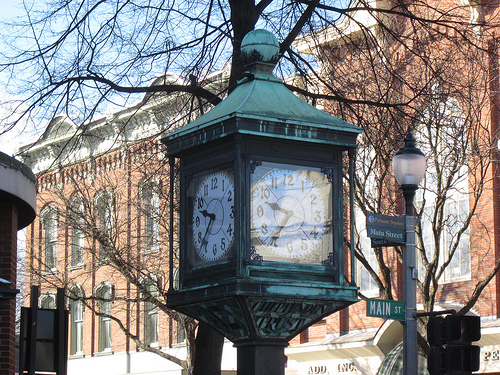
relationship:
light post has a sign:
[389, 126, 430, 374] [366, 299, 405, 320]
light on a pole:
[390, 125, 427, 195] [400, 191, 419, 374]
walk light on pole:
[425, 311, 482, 374] [400, 191, 419, 374]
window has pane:
[65, 282, 84, 359] [71, 298, 84, 324]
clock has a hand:
[159, 27, 364, 374] [201, 209, 217, 221]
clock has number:
[159, 27, 364, 374] [210, 176, 220, 191]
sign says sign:
[366, 299, 405, 320] [366, 299, 405, 320]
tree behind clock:
[17, 0, 488, 113] [159, 27, 364, 374]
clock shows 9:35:
[159, 27, 364, 374] [249, 195, 297, 250]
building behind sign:
[20, 4, 496, 364] [366, 299, 405, 320]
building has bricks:
[20, 4, 496, 364] [481, 240, 495, 252]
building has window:
[20, 4, 496, 364] [65, 282, 84, 359]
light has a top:
[390, 125, 427, 195] [394, 123, 426, 156]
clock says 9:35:
[159, 27, 364, 374] [249, 195, 297, 250]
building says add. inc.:
[20, 4, 496, 364] [304, 362, 354, 374]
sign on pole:
[366, 299, 405, 320] [400, 191, 419, 374]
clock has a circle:
[159, 27, 364, 374] [238, 26, 283, 69]